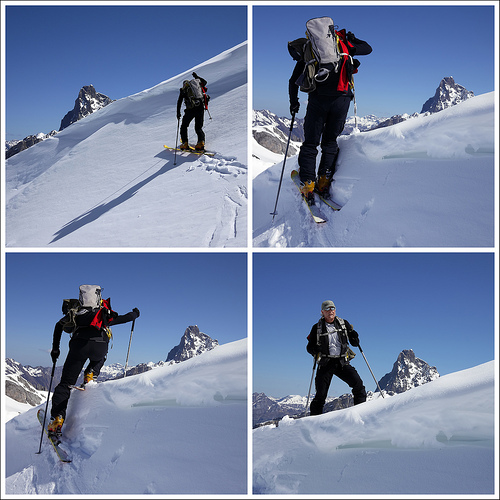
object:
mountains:
[252, 75, 474, 157]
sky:
[102, 15, 139, 47]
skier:
[176, 79, 205, 150]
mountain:
[5, 35, 245, 243]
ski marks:
[168, 144, 246, 245]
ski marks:
[353, 123, 498, 164]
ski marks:
[255, 171, 401, 246]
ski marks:
[95, 381, 246, 415]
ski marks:
[9, 410, 127, 493]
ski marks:
[259, 411, 494, 486]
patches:
[365, 119, 480, 144]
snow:
[192, 145, 243, 182]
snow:
[402, 116, 492, 244]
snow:
[103, 382, 230, 407]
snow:
[301, 410, 481, 447]